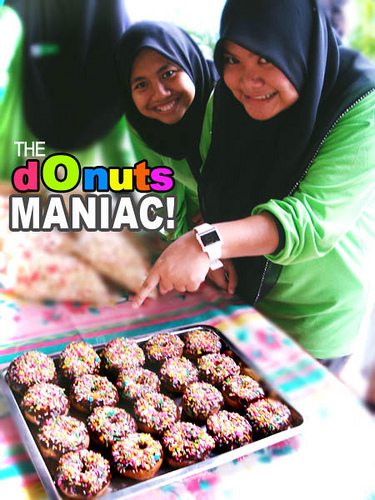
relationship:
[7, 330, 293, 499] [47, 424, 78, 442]
donut with sprinkles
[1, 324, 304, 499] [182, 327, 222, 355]
pan with donut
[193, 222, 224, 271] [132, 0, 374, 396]
watch on woman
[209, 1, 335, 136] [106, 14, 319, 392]
head covered on woman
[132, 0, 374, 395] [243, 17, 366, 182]
woman wears hijab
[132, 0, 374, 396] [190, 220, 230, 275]
woman wears watch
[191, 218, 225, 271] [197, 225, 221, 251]
watch has face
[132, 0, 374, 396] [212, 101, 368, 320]
woman has top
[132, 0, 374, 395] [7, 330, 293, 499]
woman point donut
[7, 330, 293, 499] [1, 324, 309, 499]
donut on pan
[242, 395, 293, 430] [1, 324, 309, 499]
donut on pan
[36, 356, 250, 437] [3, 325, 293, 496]
sprinkles on donuts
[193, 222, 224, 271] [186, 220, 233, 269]
watch on wrist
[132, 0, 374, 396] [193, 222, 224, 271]
woman has watch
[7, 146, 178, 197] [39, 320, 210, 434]
text reads donuts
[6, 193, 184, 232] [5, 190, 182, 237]
text print reads maniac!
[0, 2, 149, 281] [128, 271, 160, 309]
person has finger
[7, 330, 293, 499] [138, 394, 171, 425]
donut have sprinkles